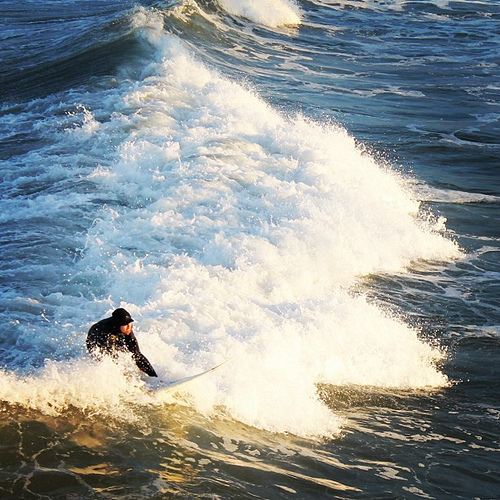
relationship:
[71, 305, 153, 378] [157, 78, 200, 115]
surfer riding wave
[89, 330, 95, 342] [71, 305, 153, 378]
wetsuit on surfer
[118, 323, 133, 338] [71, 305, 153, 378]
face of surfer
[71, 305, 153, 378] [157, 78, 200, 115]
surfer on wave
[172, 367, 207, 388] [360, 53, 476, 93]
surfboard in water